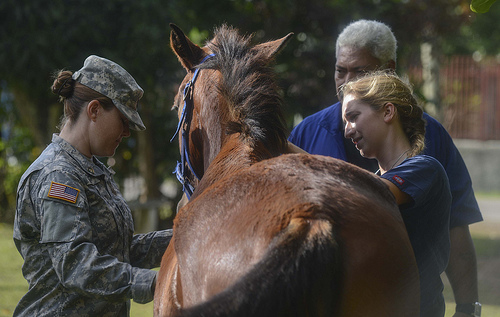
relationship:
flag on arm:
[43, 182, 88, 205] [36, 182, 159, 292]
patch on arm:
[48, 179, 82, 201] [36, 182, 159, 292]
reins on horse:
[183, 123, 202, 194] [168, 34, 413, 299]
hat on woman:
[80, 55, 156, 129] [24, 63, 144, 316]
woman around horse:
[24, 53, 173, 316] [168, 34, 413, 299]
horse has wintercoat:
[168, 34, 413, 299] [198, 144, 399, 269]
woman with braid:
[371, 81, 425, 127] [374, 67, 422, 114]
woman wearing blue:
[334, 70, 462, 317] [311, 113, 480, 208]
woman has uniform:
[24, 63, 144, 316] [26, 161, 131, 245]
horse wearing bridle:
[168, 34, 413, 299] [171, 91, 196, 175]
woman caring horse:
[24, 63, 144, 316] [168, 34, 413, 299]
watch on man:
[461, 300, 485, 314] [299, 14, 480, 218]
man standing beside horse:
[299, 14, 480, 218] [168, 34, 413, 299]